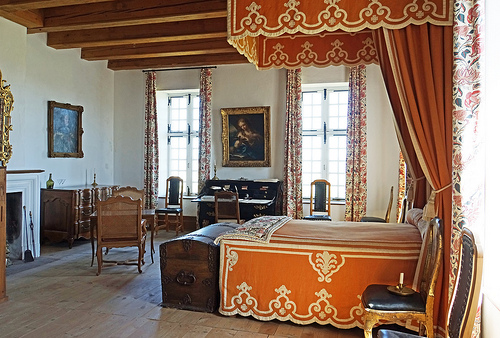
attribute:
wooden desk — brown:
[194, 193, 269, 219]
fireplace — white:
[2, 164, 60, 278]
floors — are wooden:
[26, 252, 102, 294]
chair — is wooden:
[341, 228, 498, 333]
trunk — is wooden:
[159, 194, 294, 306]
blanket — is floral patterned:
[210, 216, 291, 247]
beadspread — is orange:
[214, 217, 422, 328]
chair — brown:
[79, 188, 159, 279]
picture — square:
[216, 92, 286, 178]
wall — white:
[22, 50, 97, 88]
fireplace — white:
[0, 154, 61, 262]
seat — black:
[358, 281, 425, 313]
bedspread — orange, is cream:
[214, 207, 439, 327]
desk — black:
[187, 130, 308, 237]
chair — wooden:
[357, 217, 484, 336]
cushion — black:
[358, 280, 423, 311]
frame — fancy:
[215, 101, 276, 169]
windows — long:
[272, 61, 379, 258]